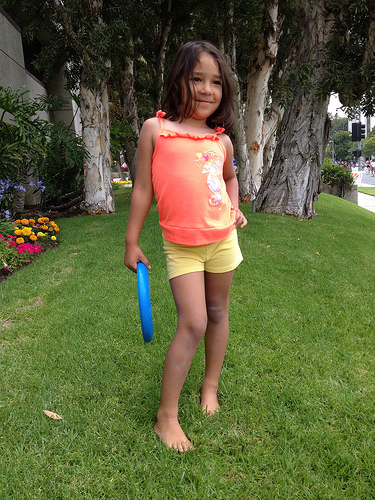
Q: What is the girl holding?
A: A frisbee.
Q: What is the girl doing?
A: Posing for the camera.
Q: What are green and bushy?
A: Tree limbs.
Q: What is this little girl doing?
A: Posing for a photo.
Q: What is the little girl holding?
A: A blue frisbee.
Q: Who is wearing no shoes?
A: Little girl.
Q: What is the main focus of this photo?
A: Little girl wearing yellow shorts and an orange tank top.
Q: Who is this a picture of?
A: A little girl with messy brown hair.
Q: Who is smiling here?
A: The little girl.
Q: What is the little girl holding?
A: A frisbee.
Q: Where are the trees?
A: Behind a girl.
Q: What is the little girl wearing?
A: Yellow shorts.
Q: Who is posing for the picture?
A: A girl.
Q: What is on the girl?
A: A pink tank top.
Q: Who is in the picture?
A: A girl.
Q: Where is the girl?
A: In the yard.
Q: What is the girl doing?
A: Posing.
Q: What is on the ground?
A: Grass.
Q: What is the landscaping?
A: Flowers.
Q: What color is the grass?
A: Green.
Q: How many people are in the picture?
A: One.